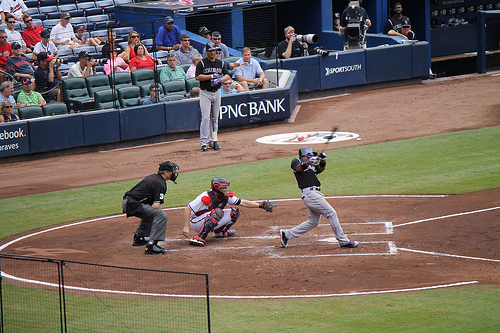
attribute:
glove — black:
[258, 197, 276, 212]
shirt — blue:
[234, 57, 264, 84]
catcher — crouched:
[179, 175, 278, 245]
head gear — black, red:
[208, 176, 230, 197]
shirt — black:
[120, 171, 159, 193]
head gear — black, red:
[204, 178, 228, 196]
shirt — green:
[18, 89, 40, 108]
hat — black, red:
[21, 76, 31, 84]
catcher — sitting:
[183, 174, 275, 242]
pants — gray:
[145, 213, 180, 231]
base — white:
[316, 235, 342, 242]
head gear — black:
[164, 157, 181, 182]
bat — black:
[321, 125, 341, 166]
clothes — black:
[121, 173, 169, 256]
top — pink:
[103, 59, 132, 74]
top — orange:
[130, 54, 155, 69]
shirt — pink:
[105, 57, 129, 75]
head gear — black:
[158, 159, 179, 182]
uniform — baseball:
[185, 191, 247, 245]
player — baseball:
[183, 26, 251, 149]